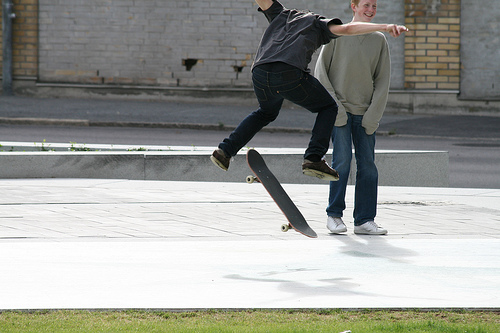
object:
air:
[222, 186, 266, 232]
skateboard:
[239, 146, 320, 252]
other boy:
[313, 0, 405, 238]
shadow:
[338, 236, 420, 278]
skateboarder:
[212, 2, 409, 194]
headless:
[298, 0, 324, 18]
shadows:
[225, 258, 386, 304]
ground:
[65, 183, 138, 281]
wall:
[413, 0, 449, 65]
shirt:
[246, 1, 345, 79]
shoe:
[210, 145, 235, 174]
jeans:
[219, 67, 339, 161]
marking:
[12, 136, 45, 153]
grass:
[64, 141, 92, 150]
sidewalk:
[128, 191, 205, 212]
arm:
[334, 22, 418, 45]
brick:
[448, 9, 463, 19]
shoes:
[323, 211, 355, 238]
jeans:
[326, 112, 386, 227]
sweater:
[311, 35, 413, 133]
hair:
[347, 1, 361, 10]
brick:
[437, 56, 459, 62]